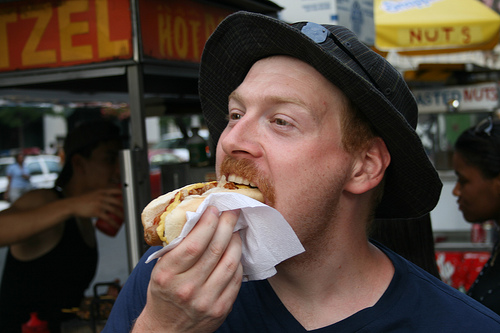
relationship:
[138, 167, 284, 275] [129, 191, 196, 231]
hotdog has ketchup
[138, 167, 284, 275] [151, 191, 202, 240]
hotdog has mustard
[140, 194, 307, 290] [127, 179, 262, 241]
napkin around hot dog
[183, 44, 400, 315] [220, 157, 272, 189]
man has mustache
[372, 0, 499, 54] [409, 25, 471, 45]
cover has nuts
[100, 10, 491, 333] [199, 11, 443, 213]
man wears hat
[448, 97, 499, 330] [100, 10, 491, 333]
person behind man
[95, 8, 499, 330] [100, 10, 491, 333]
person behind man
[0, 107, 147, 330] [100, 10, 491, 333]
person behind man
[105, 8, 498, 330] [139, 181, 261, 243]
guy eating hot dog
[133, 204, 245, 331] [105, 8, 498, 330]
hand of guy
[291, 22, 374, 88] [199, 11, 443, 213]
sunglasses on top of hat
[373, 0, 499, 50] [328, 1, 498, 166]
nuts umbrella for stand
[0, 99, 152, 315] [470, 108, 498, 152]
lady has sunglasses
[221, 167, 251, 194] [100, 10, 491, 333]
teeth of man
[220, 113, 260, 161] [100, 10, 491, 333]
nose of man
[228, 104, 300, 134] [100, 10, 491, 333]
eyes on man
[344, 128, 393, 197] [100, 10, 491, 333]
ear of man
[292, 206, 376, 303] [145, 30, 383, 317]
neck of man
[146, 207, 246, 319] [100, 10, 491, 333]
fingers of man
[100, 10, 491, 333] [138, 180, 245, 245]
man eating hot dog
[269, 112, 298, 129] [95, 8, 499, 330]
eye of person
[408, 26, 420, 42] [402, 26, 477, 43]
n on sign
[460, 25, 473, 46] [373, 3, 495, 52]
letter s on sign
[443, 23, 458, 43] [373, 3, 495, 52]
t on sign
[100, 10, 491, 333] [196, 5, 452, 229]
man wearing hat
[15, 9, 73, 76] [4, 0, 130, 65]
z on sign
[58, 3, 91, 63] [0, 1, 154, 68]
e on sign